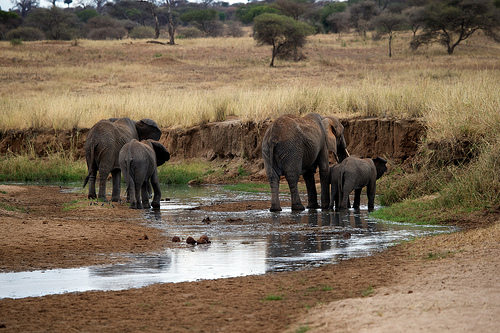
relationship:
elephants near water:
[84, 107, 389, 219] [1, 187, 476, 303]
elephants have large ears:
[84, 107, 389, 219] [136, 111, 177, 166]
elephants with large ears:
[84, 107, 389, 219] [136, 111, 177, 166]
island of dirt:
[201, 182, 301, 218] [2, 200, 496, 332]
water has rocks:
[1, 187, 476, 303] [169, 217, 220, 250]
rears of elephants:
[85, 130, 354, 194] [84, 107, 389, 219]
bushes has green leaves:
[243, 6, 320, 68] [252, 11, 313, 40]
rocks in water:
[169, 217, 220, 250] [1, 187, 476, 303]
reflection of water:
[88, 226, 359, 277] [1, 187, 476, 303]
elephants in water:
[84, 107, 389, 219] [1, 187, 476, 303]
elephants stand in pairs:
[84, 107, 389, 219] [76, 110, 169, 210]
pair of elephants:
[259, 108, 387, 212] [84, 107, 389, 219]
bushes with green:
[243, 6, 320, 68] [252, 11, 313, 40]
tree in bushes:
[164, 1, 187, 40] [13, 6, 492, 35]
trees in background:
[89, 2, 363, 28] [13, 6, 492, 35]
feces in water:
[172, 236, 213, 250] [1, 187, 476, 303]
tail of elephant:
[76, 141, 104, 194] [262, 113, 350, 213]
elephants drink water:
[84, 107, 389, 219] [1, 187, 476, 303]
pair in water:
[259, 108, 387, 212] [1, 187, 476, 303]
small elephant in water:
[116, 136, 167, 206] [1, 187, 476, 303]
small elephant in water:
[329, 155, 390, 212] [1, 187, 476, 303]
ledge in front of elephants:
[17, 122, 419, 164] [84, 107, 389, 219]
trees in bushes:
[89, 2, 363, 28] [13, 6, 492, 35]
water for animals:
[1, 187, 476, 303] [84, 107, 389, 219]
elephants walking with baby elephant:
[79, 112, 163, 204] [116, 136, 167, 206]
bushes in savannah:
[243, 6, 320, 68] [5, 32, 499, 130]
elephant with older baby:
[76, 110, 169, 210] [116, 136, 167, 206]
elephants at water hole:
[84, 107, 389, 219] [1, 187, 476, 303]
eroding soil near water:
[17, 122, 419, 164] [1, 187, 476, 303]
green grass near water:
[1, 160, 211, 184] [1, 187, 476, 303]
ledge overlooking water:
[17, 122, 419, 164] [2, 157, 456, 313]